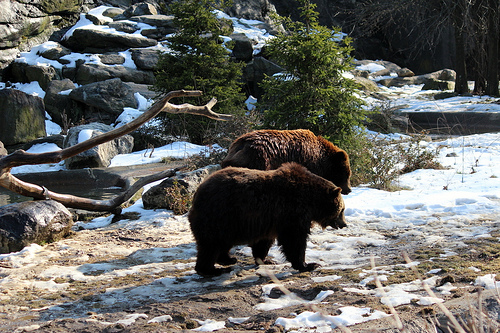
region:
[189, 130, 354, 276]
two bears walking on the ground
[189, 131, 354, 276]
two brown bears walking on the ground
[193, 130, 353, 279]
two bears walking on the ground covered with snow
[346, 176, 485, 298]
brown ground with snow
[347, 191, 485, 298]
brown ground with white snow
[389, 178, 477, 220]
the snow is white and fluffy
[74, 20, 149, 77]
rocks with snow on them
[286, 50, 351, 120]
a lush green tree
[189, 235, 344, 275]
the bear with four paws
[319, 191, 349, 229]
a brown bear's face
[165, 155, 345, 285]
brown bear in water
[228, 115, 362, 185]
brown bear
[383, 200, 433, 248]
ripples in white and brown river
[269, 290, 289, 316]
ripples in white and brown river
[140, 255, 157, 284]
ripples in white and brown river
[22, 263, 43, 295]
ripples in white and brown river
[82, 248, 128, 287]
ripples in white and brown river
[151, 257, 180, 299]
ripples in white and brown river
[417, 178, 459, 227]
ripples in white and brown river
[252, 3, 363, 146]
a green tree behind a bear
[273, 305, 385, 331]
snow on the ground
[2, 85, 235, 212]
a fallen tree on the ground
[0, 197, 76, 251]
a large rock by a fallen tree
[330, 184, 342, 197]
the ear of a bear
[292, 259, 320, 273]
the paw of a bear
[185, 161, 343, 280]
a brown bear walking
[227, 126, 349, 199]
a brown bear behind another bear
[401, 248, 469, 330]
a dry blade of grass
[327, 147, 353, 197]
the head of a bear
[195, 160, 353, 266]
A big brown bear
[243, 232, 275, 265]
A big brown bear's leg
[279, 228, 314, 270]
A big brown bear's leg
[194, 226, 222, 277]
A big brown bear's leg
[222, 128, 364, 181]
A big brown bear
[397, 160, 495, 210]
A snow filled ground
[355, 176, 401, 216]
A snow filled ground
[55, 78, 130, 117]
A big grey stone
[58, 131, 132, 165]
A big grey stone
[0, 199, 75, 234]
A big grey stone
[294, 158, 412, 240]
the head of a bear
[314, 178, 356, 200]
the ear of a bear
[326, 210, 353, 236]
the nose of a bear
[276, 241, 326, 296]
the leg of a bear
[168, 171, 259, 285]
the back legs of a bear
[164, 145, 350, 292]
the body of a bear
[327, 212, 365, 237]
the nose of a bear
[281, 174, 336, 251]
the neck of a bear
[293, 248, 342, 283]
the claws of a bear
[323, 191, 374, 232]
the eye of a bear